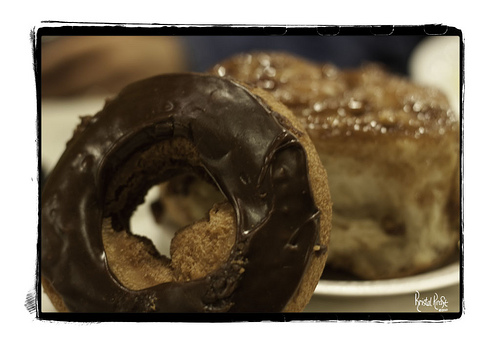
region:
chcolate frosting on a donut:
[45, 72, 312, 317]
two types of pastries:
[36, 41, 458, 315]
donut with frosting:
[38, 71, 320, 328]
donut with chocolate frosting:
[45, 69, 327, 323]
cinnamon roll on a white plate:
[170, 32, 465, 295]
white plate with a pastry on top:
[165, 216, 467, 311]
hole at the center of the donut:
[91, 148, 242, 280]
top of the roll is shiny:
[212, 49, 457, 153]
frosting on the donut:
[33, 69, 319, 318]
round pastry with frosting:
[37, 76, 335, 321]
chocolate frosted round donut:
[42, 65, 334, 312]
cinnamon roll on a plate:
[207, 45, 452, 277]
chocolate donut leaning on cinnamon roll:
[42, 67, 331, 312]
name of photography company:
[412, 288, 451, 313]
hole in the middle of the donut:
[116, 171, 226, 257]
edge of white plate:
[315, 268, 461, 295]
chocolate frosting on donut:
[232, 126, 297, 291]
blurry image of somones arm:
[47, 35, 419, 94]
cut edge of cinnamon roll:
[333, 133, 433, 276]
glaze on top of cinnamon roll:
[209, 48, 456, 138]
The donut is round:
[56, 67, 271, 339]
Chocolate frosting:
[202, 110, 304, 268]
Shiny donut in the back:
[287, 75, 467, 199]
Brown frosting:
[99, 88, 243, 177]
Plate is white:
[317, 263, 444, 319]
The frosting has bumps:
[208, 144, 315, 274]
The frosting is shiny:
[51, 192, 124, 298]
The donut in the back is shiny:
[312, 118, 426, 260]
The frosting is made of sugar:
[131, 82, 311, 275]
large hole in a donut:
[127, 148, 235, 283]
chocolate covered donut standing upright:
[39, 74, 331, 315]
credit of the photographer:
[410, 288, 455, 313]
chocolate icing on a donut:
[37, 72, 316, 312]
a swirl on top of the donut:
[242, 133, 297, 243]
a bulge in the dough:
[167, 201, 230, 272]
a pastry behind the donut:
[206, 52, 459, 280]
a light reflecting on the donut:
[70, 120, 129, 176]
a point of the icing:
[71, 110, 93, 128]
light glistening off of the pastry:
[302, 95, 397, 135]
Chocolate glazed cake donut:
[43, 65, 338, 310]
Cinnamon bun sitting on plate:
[148, 50, 460, 293]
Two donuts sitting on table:
[46, 40, 468, 325]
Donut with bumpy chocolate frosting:
[47, 62, 331, 316]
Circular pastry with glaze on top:
[156, 49, 455, 283]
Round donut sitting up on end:
[39, 67, 339, 317]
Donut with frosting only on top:
[40, 67, 331, 315]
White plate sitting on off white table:
[45, 92, 462, 314]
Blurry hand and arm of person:
[43, 32, 465, 94]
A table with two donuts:
[41, 48, 458, 310]